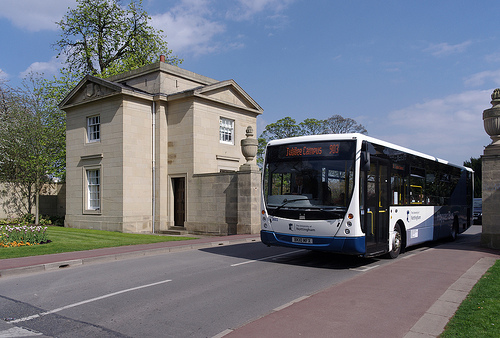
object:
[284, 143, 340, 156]
red letter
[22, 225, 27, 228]
flowers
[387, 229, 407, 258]
tire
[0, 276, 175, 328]
line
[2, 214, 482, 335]
road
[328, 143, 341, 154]
letters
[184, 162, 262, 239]
wall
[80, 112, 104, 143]
window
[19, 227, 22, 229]
flower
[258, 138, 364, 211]
windshield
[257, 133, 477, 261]
bus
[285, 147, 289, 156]
letter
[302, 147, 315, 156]
letter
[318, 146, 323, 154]
letter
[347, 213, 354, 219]
indicator light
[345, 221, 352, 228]
indicator light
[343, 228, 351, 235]
indicator light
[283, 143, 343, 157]
light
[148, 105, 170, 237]
gutter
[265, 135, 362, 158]
sign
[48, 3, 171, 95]
tree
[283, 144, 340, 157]
destination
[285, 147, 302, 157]
letter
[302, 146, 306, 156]
letter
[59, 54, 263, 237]
building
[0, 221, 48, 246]
flower bed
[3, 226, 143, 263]
landscape